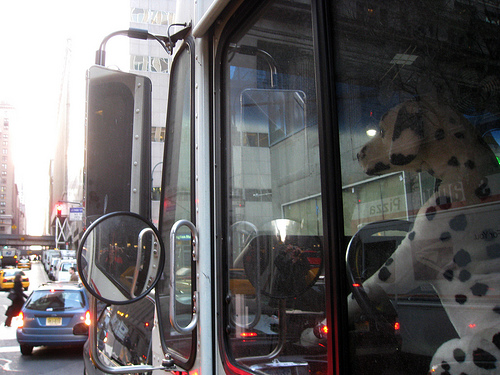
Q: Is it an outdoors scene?
A: Yes, it is outdoors.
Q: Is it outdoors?
A: Yes, it is outdoors.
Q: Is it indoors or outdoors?
A: It is outdoors.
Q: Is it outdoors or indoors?
A: It is outdoors.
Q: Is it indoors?
A: No, it is outdoors.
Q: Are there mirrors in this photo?
A: Yes, there is a mirror.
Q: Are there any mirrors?
A: Yes, there is a mirror.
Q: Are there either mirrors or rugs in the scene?
A: Yes, there is a mirror.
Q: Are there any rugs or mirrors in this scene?
A: Yes, there is a mirror.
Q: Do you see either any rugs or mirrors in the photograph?
A: Yes, there is a mirror.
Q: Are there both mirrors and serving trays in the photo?
A: No, there is a mirror but no serving trays.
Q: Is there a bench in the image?
A: No, there are no benches.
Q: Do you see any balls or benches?
A: No, there are no benches or balls.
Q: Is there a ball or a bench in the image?
A: No, there are no benches or balls.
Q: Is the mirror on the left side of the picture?
A: Yes, the mirror is on the left of the image.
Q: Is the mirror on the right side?
A: No, the mirror is on the left of the image.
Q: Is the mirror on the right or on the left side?
A: The mirror is on the left of the image.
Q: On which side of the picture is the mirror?
A: The mirror is on the left of the image.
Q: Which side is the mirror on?
A: The mirror is on the left of the image.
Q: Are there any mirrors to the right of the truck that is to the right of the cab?
A: Yes, there is a mirror to the right of the truck.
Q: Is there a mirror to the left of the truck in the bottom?
A: No, the mirror is to the right of the truck.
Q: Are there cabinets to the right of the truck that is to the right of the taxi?
A: No, there is a mirror to the right of the truck.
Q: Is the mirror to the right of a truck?
A: Yes, the mirror is to the right of a truck.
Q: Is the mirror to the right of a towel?
A: No, the mirror is to the right of a truck.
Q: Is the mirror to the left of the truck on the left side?
A: No, the mirror is to the right of the truck.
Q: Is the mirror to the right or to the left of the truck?
A: The mirror is to the right of the truck.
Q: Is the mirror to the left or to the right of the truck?
A: The mirror is to the right of the truck.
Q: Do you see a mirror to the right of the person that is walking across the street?
A: Yes, there is a mirror to the right of the person.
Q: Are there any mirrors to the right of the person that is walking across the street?
A: Yes, there is a mirror to the right of the person.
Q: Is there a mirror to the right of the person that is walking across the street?
A: Yes, there is a mirror to the right of the person.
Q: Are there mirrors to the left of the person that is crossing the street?
A: No, the mirror is to the right of the person.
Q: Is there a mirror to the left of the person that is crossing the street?
A: No, the mirror is to the right of the person.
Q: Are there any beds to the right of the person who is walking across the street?
A: No, there is a mirror to the right of the person.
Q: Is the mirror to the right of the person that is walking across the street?
A: Yes, the mirror is to the right of the person.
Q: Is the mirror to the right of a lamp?
A: No, the mirror is to the right of the person.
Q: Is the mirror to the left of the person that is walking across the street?
A: No, the mirror is to the right of the person.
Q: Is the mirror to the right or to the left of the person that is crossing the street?
A: The mirror is to the right of the person.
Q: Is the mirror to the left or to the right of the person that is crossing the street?
A: The mirror is to the right of the person.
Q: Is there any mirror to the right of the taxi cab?
A: Yes, there is a mirror to the right of the taxi cab.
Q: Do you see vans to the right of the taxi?
A: No, there is a mirror to the right of the taxi.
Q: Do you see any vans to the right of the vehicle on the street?
A: No, there is a mirror to the right of the taxi.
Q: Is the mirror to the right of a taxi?
A: Yes, the mirror is to the right of a taxi.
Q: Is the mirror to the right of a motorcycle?
A: No, the mirror is to the right of a taxi.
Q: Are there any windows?
A: Yes, there is a window.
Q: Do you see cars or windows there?
A: Yes, there is a window.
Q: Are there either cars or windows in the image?
A: Yes, there is a window.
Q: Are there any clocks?
A: No, there are no clocks.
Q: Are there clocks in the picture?
A: No, there are no clocks.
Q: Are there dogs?
A: Yes, there is a dog.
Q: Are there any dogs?
A: Yes, there is a dog.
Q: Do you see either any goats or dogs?
A: Yes, there is a dog.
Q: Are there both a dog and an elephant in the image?
A: No, there is a dog but no elephants.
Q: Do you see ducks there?
A: No, there are no ducks.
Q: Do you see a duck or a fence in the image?
A: No, there are no ducks or fences.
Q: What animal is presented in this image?
A: The animal is a dog.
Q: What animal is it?
A: The animal is a dog.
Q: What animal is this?
A: This is a dog.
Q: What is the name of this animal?
A: This is a dog.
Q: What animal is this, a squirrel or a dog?
A: This is a dog.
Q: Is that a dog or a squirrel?
A: That is a dog.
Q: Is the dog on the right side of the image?
A: Yes, the dog is on the right of the image.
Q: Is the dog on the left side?
A: No, the dog is on the right of the image.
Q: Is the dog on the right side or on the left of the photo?
A: The dog is on the right of the image.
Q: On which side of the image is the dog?
A: The dog is on the right of the image.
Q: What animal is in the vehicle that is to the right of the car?
A: The dog is in the bus.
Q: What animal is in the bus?
A: The dog is in the bus.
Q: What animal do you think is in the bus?
A: The animal is a dog.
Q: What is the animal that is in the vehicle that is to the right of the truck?
A: The animal is a dog.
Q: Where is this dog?
A: The dog is in the bus.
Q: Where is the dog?
A: The dog is in the bus.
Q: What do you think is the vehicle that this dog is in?
A: The vehicle is a bus.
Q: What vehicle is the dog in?
A: The dog is in the bus.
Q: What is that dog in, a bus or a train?
A: The dog is in a bus.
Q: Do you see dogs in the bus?
A: Yes, there is a dog in the bus.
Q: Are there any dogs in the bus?
A: Yes, there is a dog in the bus.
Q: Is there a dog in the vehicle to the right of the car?
A: Yes, there is a dog in the bus.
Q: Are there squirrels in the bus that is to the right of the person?
A: No, there is a dog in the bus.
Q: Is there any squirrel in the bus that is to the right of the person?
A: No, there is a dog in the bus.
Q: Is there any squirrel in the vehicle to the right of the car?
A: No, there is a dog in the bus.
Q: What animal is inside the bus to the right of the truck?
A: The dog is inside the bus.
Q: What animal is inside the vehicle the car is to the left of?
A: The dog is inside the bus.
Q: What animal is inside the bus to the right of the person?
A: The animal is a dog.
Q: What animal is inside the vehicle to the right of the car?
A: The animal is a dog.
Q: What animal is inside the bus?
A: The animal is a dog.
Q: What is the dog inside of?
A: The dog is inside the bus.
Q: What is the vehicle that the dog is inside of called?
A: The vehicle is a bus.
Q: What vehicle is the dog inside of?
A: The dog is inside the bus.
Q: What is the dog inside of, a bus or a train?
A: The dog is inside a bus.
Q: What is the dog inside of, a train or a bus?
A: The dog is inside a bus.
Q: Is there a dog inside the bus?
A: Yes, there is a dog inside the bus.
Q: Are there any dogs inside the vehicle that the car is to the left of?
A: Yes, there is a dog inside the bus.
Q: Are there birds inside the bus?
A: No, there is a dog inside the bus.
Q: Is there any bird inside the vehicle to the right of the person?
A: No, there is a dog inside the bus.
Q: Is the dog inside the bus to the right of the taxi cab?
A: Yes, the dog is inside the bus.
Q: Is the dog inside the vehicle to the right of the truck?
A: Yes, the dog is inside the bus.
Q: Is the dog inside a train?
A: No, the dog is inside the bus.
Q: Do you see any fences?
A: No, there are no fences.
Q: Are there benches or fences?
A: No, there are no fences or benches.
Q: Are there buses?
A: Yes, there is a bus.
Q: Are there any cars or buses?
A: Yes, there is a bus.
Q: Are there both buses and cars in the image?
A: Yes, there are both a bus and a car.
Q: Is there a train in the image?
A: No, there are no trains.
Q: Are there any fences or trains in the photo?
A: No, there are no trains or fences.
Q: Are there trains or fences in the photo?
A: No, there are no trains or fences.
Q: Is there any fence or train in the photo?
A: No, there are no trains or fences.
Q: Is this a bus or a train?
A: This is a bus.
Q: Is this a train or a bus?
A: This is a bus.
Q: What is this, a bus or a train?
A: This is a bus.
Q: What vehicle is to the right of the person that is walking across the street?
A: The vehicle is a bus.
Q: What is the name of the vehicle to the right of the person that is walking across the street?
A: The vehicle is a bus.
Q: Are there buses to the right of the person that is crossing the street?
A: Yes, there is a bus to the right of the person.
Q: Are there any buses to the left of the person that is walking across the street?
A: No, the bus is to the right of the person.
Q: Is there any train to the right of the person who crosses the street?
A: No, there is a bus to the right of the person.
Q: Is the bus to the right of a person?
A: Yes, the bus is to the right of a person.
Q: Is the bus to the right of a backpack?
A: No, the bus is to the right of a person.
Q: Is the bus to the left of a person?
A: No, the bus is to the right of a person.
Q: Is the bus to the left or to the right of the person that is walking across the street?
A: The bus is to the right of the person.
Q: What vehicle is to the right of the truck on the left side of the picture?
A: The vehicle is a bus.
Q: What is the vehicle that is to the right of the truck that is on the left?
A: The vehicle is a bus.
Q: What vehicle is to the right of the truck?
A: The vehicle is a bus.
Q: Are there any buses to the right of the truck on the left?
A: Yes, there is a bus to the right of the truck.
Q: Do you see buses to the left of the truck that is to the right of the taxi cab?
A: No, the bus is to the right of the truck.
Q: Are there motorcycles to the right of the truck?
A: No, there is a bus to the right of the truck.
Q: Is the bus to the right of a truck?
A: Yes, the bus is to the right of a truck.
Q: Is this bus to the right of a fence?
A: No, the bus is to the right of a truck.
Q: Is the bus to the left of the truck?
A: No, the bus is to the right of the truck.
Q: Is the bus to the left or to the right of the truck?
A: The bus is to the right of the truck.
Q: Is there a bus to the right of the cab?
A: Yes, there is a bus to the right of the cab.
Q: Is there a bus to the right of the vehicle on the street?
A: Yes, there is a bus to the right of the cab.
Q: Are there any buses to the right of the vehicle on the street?
A: Yes, there is a bus to the right of the cab.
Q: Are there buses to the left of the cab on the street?
A: No, the bus is to the right of the cab.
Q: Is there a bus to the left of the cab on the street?
A: No, the bus is to the right of the cab.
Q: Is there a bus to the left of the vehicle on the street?
A: No, the bus is to the right of the cab.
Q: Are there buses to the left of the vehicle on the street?
A: No, the bus is to the right of the cab.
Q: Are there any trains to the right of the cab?
A: No, there is a bus to the right of the cab.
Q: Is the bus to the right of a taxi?
A: Yes, the bus is to the right of a taxi.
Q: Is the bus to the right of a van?
A: No, the bus is to the right of a taxi.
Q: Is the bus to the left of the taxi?
A: No, the bus is to the right of the taxi.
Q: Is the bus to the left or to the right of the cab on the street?
A: The bus is to the right of the taxi.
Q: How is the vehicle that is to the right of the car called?
A: The vehicle is a bus.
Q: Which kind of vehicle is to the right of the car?
A: The vehicle is a bus.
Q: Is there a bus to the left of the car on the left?
A: No, the bus is to the right of the car.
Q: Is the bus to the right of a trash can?
A: No, the bus is to the right of the car.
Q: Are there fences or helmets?
A: No, there are no fences or helmets.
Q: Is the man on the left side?
A: Yes, the man is on the left of the image.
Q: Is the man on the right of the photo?
A: No, the man is on the left of the image.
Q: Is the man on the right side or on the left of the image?
A: The man is on the left of the image.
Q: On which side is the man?
A: The man is on the left of the image.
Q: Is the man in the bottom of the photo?
A: Yes, the man is in the bottom of the image.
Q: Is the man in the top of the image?
A: No, the man is in the bottom of the image.